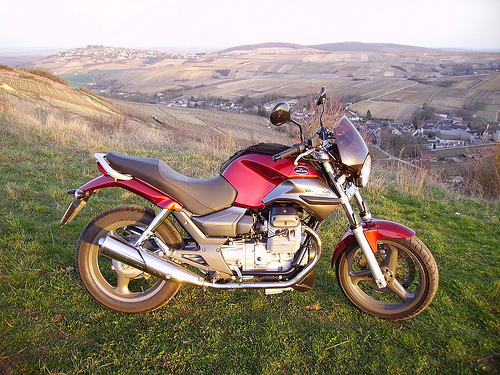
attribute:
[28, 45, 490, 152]
land — farm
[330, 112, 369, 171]
visor — small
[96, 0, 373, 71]
sky — white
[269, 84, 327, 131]
mirrors — black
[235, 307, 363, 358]
grass — green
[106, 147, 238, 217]
seat — black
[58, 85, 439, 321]
bike — red